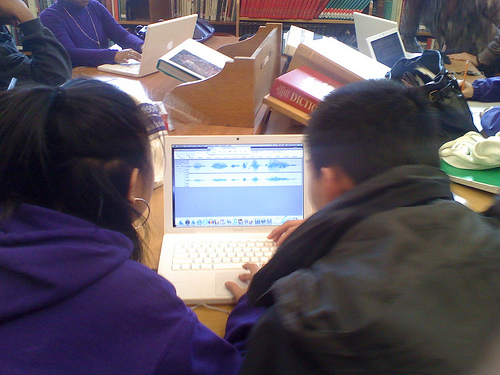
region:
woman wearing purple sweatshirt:
[0, 77, 269, 373]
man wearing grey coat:
[240, 77, 498, 374]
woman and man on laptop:
[1, 75, 498, 374]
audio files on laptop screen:
[174, 157, 301, 184]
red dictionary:
[272, 66, 346, 114]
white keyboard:
[173, 241, 280, 268]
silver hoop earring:
[130, 197, 149, 228]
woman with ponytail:
[0, 77, 262, 373]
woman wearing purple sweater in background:
[35, 0, 144, 70]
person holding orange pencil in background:
[457, 59, 498, 103]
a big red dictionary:
[265, 62, 351, 131]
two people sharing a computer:
[18, 63, 498, 274]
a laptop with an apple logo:
[87, 16, 256, 93]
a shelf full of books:
[105, 0, 424, 50]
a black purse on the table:
[370, 41, 489, 151]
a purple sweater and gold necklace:
[42, 4, 152, 70]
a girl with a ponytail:
[2, 71, 228, 373]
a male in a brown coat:
[259, 71, 489, 371]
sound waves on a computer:
[160, 128, 337, 218]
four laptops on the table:
[77, 9, 481, 319]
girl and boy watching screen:
[8, 75, 495, 357]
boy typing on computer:
[207, 83, 499, 366]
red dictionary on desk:
[259, 59, 351, 123]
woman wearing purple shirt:
[32, 0, 152, 72]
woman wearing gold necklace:
[54, 1, 126, 68]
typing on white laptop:
[129, 127, 338, 314]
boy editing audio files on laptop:
[134, 63, 491, 370]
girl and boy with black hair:
[7, 77, 495, 373]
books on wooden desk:
[147, 37, 409, 138]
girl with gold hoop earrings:
[12, 81, 175, 251]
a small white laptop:
[160, 128, 326, 304]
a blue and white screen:
[171, 146, 304, 222]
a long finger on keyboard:
[241, 260, 260, 276]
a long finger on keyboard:
[266, 218, 303, 241]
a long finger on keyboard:
[275, 223, 302, 248]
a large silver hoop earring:
[125, 195, 153, 228]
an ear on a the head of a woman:
[7, 76, 154, 230]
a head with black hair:
[305, 78, 439, 196]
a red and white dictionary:
[271, 63, 344, 114]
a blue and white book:
[155, 35, 232, 81]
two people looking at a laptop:
[5, 75, 495, 366]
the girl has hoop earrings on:
[125, 191, 151, 231]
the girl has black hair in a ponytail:
[5, 72, 157, 238]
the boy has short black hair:
[298, 75, 446, 193]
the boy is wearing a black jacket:
[238, 195, 495, 370]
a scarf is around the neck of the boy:
[241, 162, 457, 303]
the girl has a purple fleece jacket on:
[2, 200, 267, 370]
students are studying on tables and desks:
[8, 5, 498, 361]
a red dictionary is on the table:
[272, 65, 343, 125]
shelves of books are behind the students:
[41, 2, 394, 39]